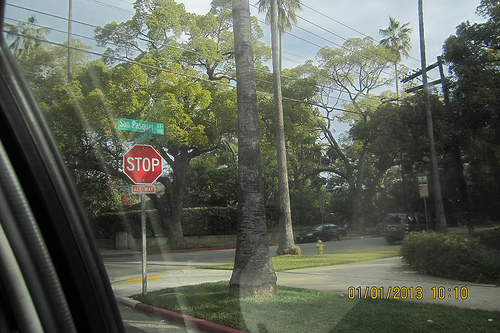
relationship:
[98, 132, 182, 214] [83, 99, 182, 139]
sign with sign